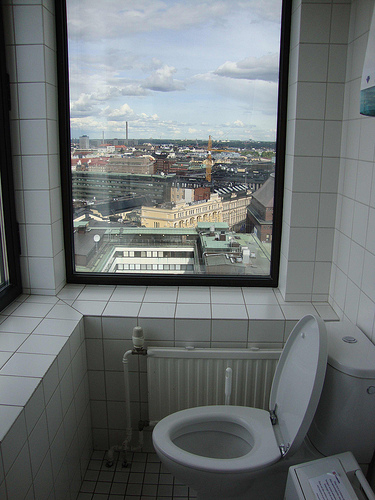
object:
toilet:
[151, 314, 374, 499]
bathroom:
[3, 0, 372, 499]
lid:
[269, 313, 331, 459]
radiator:
[106, 327, 284, 467]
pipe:
[122, 352, 133, 443]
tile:
[78, 451, 191, 498]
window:
[72, 3, 271, 276]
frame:
[56, 0, 295, 287]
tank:
[311, 323, 374, 471]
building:
[140, 196, 254, 226]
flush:
[341, 333, 360, 346]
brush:
[224, 368, 235, 404]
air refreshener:
[359, 12, 375, 116]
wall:
[332, 0, 374, 340]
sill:
[64, 285, 336, 319]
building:
[124, 118, 132, 157]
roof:
[113, 222, 268, 273]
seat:
[152, 405, 283, 473]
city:
[73, 122, 272, 276]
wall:
[12, 2, 61, 300]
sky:
[74, 0, 276, 120]